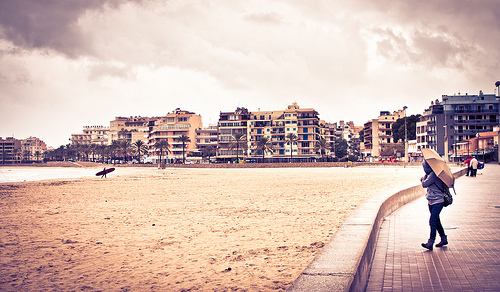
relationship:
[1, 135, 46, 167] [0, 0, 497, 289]
building far away from scene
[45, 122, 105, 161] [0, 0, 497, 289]
building far away from scene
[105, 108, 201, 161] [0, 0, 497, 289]
building far away from scene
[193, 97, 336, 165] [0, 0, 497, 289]
building far away from scene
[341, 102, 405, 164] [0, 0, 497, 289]
building far away from scene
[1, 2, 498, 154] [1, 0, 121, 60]
sky covered with cloud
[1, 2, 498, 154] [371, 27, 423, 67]
sky covered with cloud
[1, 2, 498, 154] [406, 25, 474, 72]
sky covered with cloud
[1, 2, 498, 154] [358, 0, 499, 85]
sky covered with cloud